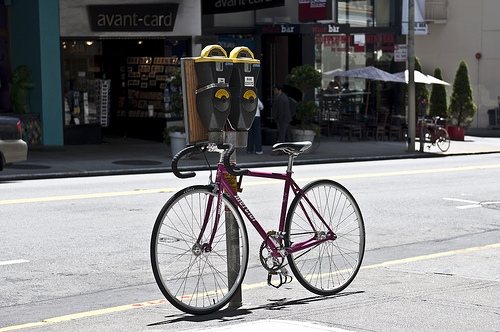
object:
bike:
[149, 138, 367, 317]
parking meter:
[177, 42, 263, 309]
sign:
[85, 2, 180, 33]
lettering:
[143, 14, 173, 27]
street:
[1, 150, 499, 329]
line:
[0, 193, 94, 204]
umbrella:
[323, 66, 408, 84]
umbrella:
[392, 70, 452, 85]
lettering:
[331, 46, 336, 53]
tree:
[446, 60, 476, 127]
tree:
[427, 67, 448, 124]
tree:
[413, 56, 430, 117]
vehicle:
[0, 115, 26, 171]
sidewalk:
[2, 238, 499, 329]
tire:
[284, 178, 366, 297]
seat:
[272, 140, 312, 155]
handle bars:
[171, 145, 198, 179]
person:
[269, 84, 292, 154]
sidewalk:
[0, 133, 378, 179]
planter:
[448, 125, 465, 141]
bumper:
[0, 139, 28, 162]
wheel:
[149, 185, 249, 316]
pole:
[406, 0, 418, 154]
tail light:
[16, 120, 21, 132]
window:
[107, 37, 192, 120]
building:
[0, 1, 212, 147]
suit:
[272, 92, 292, 123]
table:
[350, 120, 386, 125]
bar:
[240, 0, 405, 135]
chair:
[365, 109, 390, 141]